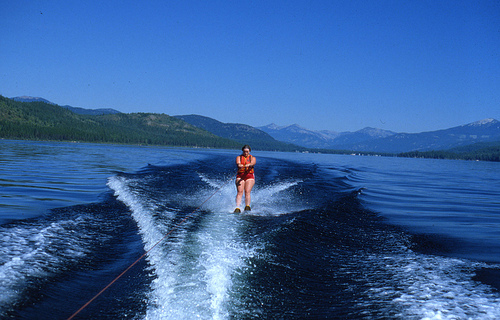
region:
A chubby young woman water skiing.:
[232, 143, 255, 213]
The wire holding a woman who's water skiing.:
[66, 176, 233, 318]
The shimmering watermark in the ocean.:
[102, 168, 311, 316]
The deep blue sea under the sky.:
[0, 134, 499, 318]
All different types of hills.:
[0, 92, 496, 162]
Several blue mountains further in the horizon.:
[257, 119, 499, 154]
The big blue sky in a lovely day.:
[0, 0, 499, 112]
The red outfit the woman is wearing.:
[237, 154, 256, 181]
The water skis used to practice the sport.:
[232, 204, 253, 216]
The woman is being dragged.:
[67, 144, 257, 318]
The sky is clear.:
[26, 25, 457, 77]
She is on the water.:
[206, 145, 293, 236]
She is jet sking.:
[170, 139, 304, 261]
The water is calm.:
[336, 159, 474, 286]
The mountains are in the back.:
[3, 83, 480, 154]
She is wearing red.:
[200, 138, 278, 235]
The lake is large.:
[6, 32, 448, 317]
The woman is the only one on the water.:
[102, 103, 490, 313]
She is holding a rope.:
[56, 129, 351, 319]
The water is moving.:
[50, 136, 491, 318]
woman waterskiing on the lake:
[230, 142, 259, 218]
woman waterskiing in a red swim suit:
[228, 140, 261, 215]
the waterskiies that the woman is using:
[230, 204, 255, 219]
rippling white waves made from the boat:
[108, 175, 177, 280]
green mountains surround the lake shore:
[2, 97, 234, 147]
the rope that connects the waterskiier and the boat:
[67, 164, 249, 314]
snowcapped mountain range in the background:
[258, 120, 496, 156]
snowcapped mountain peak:
[468, 115, 496, 128]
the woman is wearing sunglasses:
[233, 138, 253, 159]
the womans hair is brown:
[237, 140, 254, 156]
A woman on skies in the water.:
[234, 141, 256, 216]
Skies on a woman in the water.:
[228, 203, 250, 216]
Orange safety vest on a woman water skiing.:
[235, 150, 252, 175]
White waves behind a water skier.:
[197, 169, 305, 202]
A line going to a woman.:
[67, 165, 242, 319]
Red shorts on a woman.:
[235, 169, 257, 181]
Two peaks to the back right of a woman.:
[252, 120, 326, 150]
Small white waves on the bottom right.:
[365, 249, 499, 319]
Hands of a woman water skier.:
[235, 160, 250, 170]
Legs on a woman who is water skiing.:
[232, 176, 255, 209]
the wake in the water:
[140, 207, 265, 314]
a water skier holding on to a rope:
[220, 135, 270, 215]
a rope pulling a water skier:
[60, 156, 247, 312]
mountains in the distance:
[261, 116, 396, 151]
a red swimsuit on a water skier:
[235, 170, 255, 182]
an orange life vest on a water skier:
[236, 151, 251, 162]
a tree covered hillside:
[5, 116, 96, 136]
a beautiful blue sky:
[0, 3, 496, 124]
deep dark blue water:
[4, 137, 495, 318]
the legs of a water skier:
[232, 176, 258, 205]